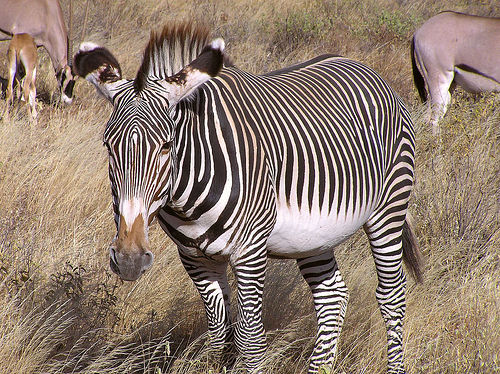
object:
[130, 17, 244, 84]
hairs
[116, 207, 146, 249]
spot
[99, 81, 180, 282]
face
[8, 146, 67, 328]
grass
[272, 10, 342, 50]
plant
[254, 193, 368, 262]
belly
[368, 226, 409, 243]
strip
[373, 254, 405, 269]
strip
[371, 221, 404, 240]
strip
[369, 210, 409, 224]
strip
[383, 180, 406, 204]
strip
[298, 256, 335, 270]
strip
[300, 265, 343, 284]
strip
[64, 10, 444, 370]
zebra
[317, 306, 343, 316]
strip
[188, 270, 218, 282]
strip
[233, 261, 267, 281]
strip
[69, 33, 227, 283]
head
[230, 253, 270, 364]
leg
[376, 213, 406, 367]
leg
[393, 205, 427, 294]
tail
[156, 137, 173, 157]
eye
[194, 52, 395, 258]
body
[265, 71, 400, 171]
skin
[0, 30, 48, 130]
animal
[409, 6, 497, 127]
animal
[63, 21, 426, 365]
animal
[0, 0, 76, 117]
animal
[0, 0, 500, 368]
forest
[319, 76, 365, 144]
stripe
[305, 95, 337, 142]
stripe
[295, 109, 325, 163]
stripe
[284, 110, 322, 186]
stripe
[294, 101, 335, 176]
stripe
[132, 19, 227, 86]
mane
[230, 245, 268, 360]
leg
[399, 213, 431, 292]
tail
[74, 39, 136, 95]
ears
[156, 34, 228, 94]
ear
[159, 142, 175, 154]
eye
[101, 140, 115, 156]
eye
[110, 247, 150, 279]
nose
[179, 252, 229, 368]
leg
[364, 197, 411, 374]
hind leg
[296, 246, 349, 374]
hind leg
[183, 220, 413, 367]
legs